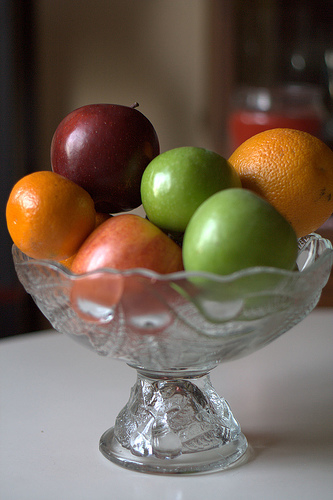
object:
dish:
[12, 207, 331, 476]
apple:
[50, 102, 159, 214]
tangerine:
[5, 170, 95, 262]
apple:
[140, 144, 239, 233]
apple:
[179, 185, 299, 301]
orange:
[228, 127, 331, 238]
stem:
[128, 99, 141, 110]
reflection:
[10, 185, 44, 226]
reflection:
[62, 121, 92, 170]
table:
[0, 309, 332, 498]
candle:
[225, 82, 321, 157]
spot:
[312, 183, 332, 206]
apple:
[68, 211, 198, 335]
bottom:
[97, 371, 247, 475]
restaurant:
[0, 1, 330, 498]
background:
[1, 0, 333, 500]